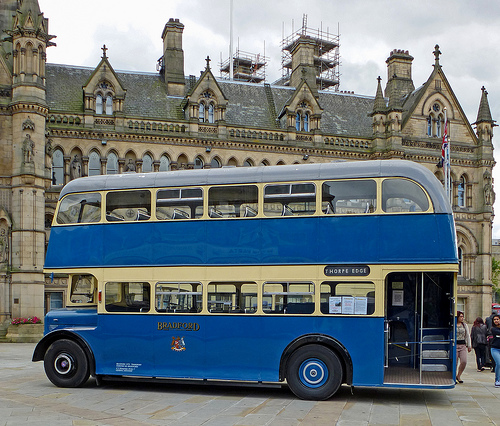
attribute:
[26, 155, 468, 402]
bus — double decker, blue, yellow, on street, city tour bus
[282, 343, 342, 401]
wheel — black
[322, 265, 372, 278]
sign — black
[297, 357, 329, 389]
hubcap — blue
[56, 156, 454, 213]
roof — grey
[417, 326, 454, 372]
steps — grey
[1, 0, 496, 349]
building — large, old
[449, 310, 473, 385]
person — walking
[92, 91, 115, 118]
window — arched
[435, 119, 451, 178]
flag — british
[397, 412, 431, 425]
slab — stone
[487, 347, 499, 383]
jeans — blue